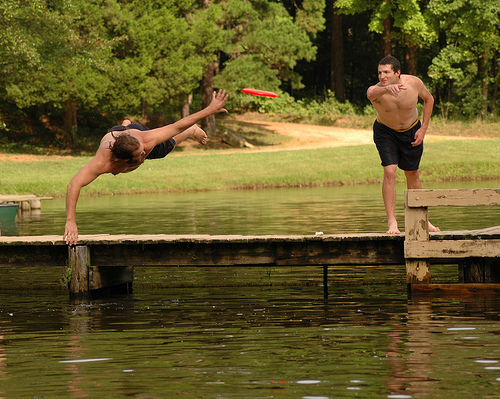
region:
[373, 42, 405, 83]
head of a person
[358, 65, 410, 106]
arm of a person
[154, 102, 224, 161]
arm of a person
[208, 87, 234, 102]
fingers of a person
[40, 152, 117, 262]
arm of a person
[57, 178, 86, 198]
elbow of a person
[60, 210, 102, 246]
hand of a person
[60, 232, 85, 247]
fingers of a person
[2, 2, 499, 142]
green leaves on trees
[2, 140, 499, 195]
green grass of water bank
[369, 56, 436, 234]
shirtless man bending over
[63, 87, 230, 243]
man horizontal in the air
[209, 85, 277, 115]
hand reaching for frisbee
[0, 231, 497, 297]
wood dock over water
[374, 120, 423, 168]
black shorts on man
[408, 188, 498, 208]
worn paint on wood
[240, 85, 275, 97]
red frisbee in mid air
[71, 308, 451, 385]
The lake water below the doc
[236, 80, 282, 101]
The frisbee is in the air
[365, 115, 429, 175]
The man is wearing shorts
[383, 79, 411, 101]
The hand of the man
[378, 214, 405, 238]
The foot of the man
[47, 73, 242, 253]
The man is in the air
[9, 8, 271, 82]
The leaves on the tree are green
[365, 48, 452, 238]
The man is pointing forward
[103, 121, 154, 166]
The head of the man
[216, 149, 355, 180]
The grass is short and green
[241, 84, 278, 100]
red frisbee in the air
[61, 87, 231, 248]
man in black swimming trunks who is about to get wet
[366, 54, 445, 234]
man in black swimming trunks with right arm extended in front of him and standing on a dock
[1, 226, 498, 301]
brown wooden dock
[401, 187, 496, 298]
partial brown wooden fence that is wet on its lower portion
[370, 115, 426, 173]
black swimming shorts with yellow waistband trim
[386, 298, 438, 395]
water reflection mostly of a man's leg and a fence post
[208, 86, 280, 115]
left hand that is open to catch the frisbee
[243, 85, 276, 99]
a red frisbee is in the air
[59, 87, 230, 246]
a man is jumping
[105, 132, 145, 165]
man has a head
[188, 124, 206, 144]
man has a foot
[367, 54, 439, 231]
man is leaning forward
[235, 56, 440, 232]
man is throwing a frisbee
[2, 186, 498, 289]
a wooden dock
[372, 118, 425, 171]
a man's black shorts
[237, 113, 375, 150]
a dirt road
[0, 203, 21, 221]
a green metal boat